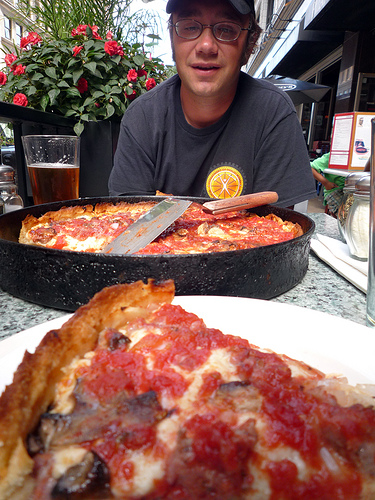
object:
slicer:
[99, 189, 280, 253]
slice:
[1, 274, 375, 500]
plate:
[0, 293, 375, 393]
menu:
[328, 112, 353, 169]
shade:
[266, 71, 335, 111]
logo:
[204, 161, 248, 199]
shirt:
[105, 70, 317, 211]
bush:
[3, 22, 165, 124]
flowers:
[27, 31, 41, 45]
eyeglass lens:
[175, 20, 201, 39]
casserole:
[0, 279, 372, 500]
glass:
[19, 135, 80, 206]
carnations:
[2, 24, 164, 137]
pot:
[0, 101, 114, 208]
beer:
[27, 161, 79, 205]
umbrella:
[267, 74, 331, 106]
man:
[108, 0, 320, 211]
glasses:
[168, 17, 252, 43]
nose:
[195, 31, 218, 55]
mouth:
[189, 61, 221, 76]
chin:
[189, 80, 219, 97]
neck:
[179, 77, 236, 120]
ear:
[245, 31, 259, 63]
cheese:
[63, 348, 307, 498]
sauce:
[0, 279, 375, 498]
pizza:
[0, 274, 375, 500]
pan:
[0, 194, 315, 313]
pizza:
[18, 203, 303, 254]